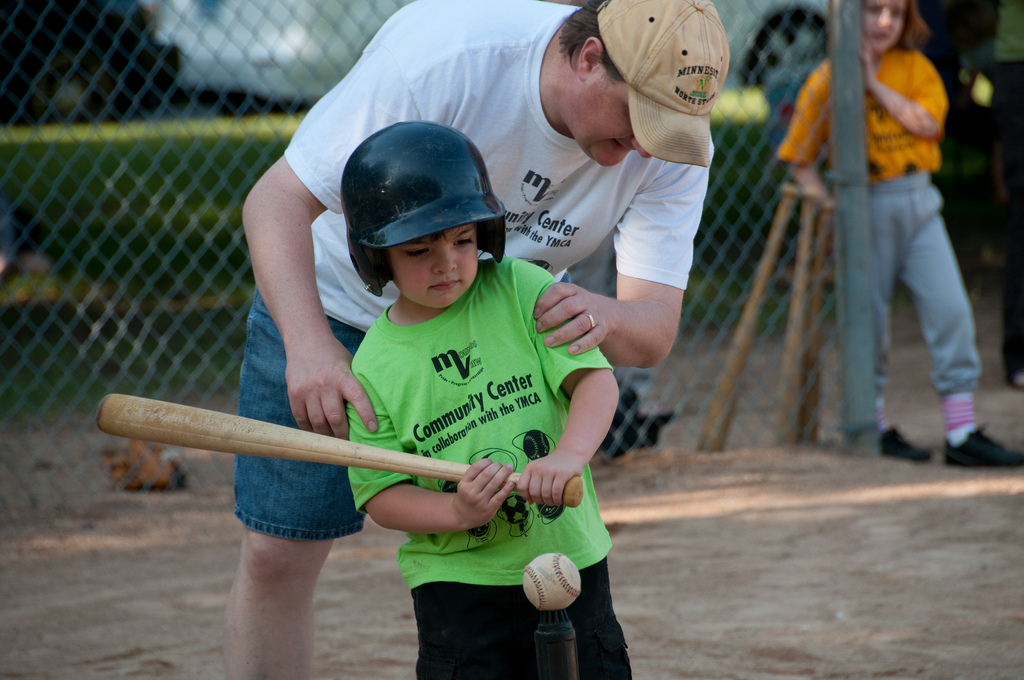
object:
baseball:
[521, 553, 581, 611]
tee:
[532, 610, 579, 678]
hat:
[595, 0, 730, 167]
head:
[551, 0, 731, 167]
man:
[233, 0, 726, 680]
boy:
[339, 122, 630, 680]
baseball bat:
[95, 392, 583, 508]